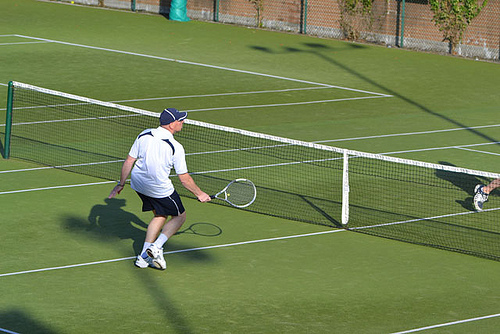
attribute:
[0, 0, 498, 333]
court — green, lined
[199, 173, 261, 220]
racket — silver